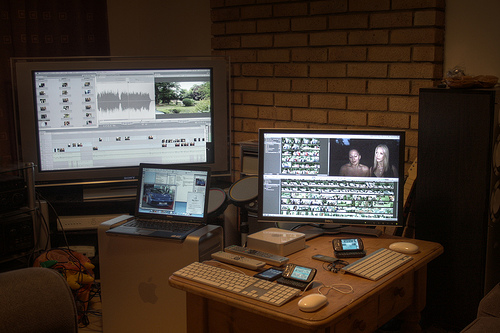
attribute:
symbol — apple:
[135, 274, 160, 307]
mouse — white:
[291, 287, 341, 325]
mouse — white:
[297, 292, 327, 312]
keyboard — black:
[117, 214, 198, 241]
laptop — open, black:
[108, 166, 210, 243]